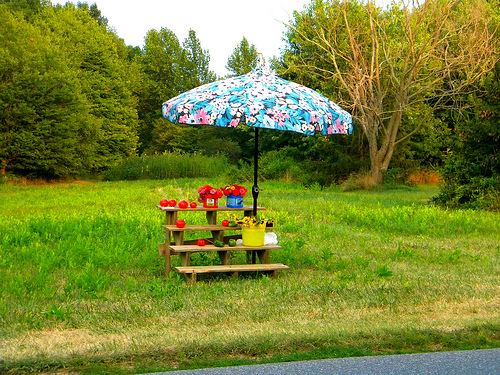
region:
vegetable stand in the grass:
[131, 175, 293, 287]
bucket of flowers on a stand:
[237, 214, 275, 250]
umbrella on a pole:
[159, 55, 364, 142]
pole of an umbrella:
[251, 134, 263, 214]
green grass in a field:
[23, 204, 132, 271]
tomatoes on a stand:
[156, 195, 200, 218]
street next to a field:
[319, 350, 492, 373]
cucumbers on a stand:
[206, 234, 236, 251]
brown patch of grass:
[15, 330, 104, 352]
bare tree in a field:
[316, 4, 476, 108]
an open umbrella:
[158, 60, 353, 140]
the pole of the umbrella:
[250, 127, 262, 212]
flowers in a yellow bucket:
[230, 212, 268, 249]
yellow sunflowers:
[236, 213, 271, 223]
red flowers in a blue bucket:
[225, 180, 247, 208]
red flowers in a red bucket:
[198, 182, 221, 205]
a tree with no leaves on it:
[308, 5, 485, 187]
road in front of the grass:
[144, 342, 496, 372]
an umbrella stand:
[161, 54, 356, 277]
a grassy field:
[3, 183, 496, 367]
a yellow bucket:
[241, 216, 266, 249]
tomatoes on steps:
[158, 193, 231, 250]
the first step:
[174, 260, 287, 283]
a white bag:
[239, 232, 279, 249]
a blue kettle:
[223, 181, 245, 208]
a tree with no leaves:
[276, 0, 499, 188]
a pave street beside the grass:
[149, 351, 499, 373]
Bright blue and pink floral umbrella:
[159, 63, 352, 216]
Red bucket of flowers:
[198, 185, 224, 208]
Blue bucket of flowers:
[225, 180, 250, 211]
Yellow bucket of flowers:
[226, 210, 268, 247]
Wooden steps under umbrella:
[158, 191, 290, 284]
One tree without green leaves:
[290, 1, 499, 182]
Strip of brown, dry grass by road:
[3, 282, 498, 364]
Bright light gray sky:
[49, 0, 424, 76]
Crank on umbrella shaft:
[251, 184, 266, 196]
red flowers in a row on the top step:
[156, 198, 199, 208]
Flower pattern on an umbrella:
[161, 63, 353, 138]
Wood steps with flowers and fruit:
[154, 180, 289, 284]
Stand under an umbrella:
[154, 63, 355, 281]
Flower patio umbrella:
[162, 62, 354, 282]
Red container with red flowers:
[196, 183, 224, 207]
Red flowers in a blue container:
[220, 180, 247, 206]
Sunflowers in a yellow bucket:
[227, 209, 267, 248]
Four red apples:
[157, 195, 197, 211]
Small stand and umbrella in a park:
[149, 60, 354, 283]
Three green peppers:
[211, 217, 239, 248]